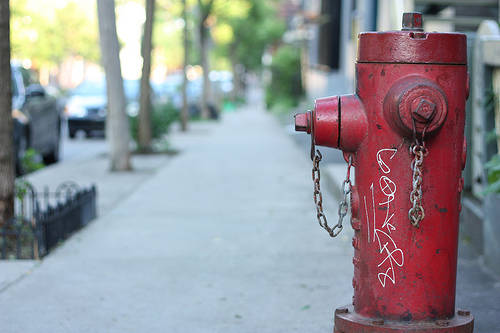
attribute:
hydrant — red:
[274, 10, 476, 331]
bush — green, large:
[268, 55, 305, 107]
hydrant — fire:
[288, 12, 483, 331]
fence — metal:
[28, 177, 135, 295]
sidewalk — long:
[151, 122, 318, 327]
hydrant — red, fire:
[314, 14, 449, 331]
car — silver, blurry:
[54, 50, 158, 153]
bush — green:
[122, 97, 182, 154]